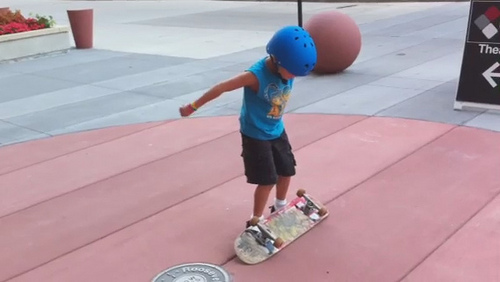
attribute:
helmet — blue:
[267, 23, 325, 72]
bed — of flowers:
[0, 6, 74, 60]